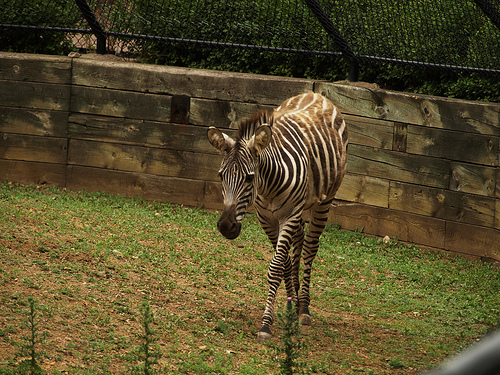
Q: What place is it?
A: It is a field.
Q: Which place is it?
A: It is a field.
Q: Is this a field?
A: Yes, it is a field.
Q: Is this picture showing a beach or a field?
A: It is showing a field.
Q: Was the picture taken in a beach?
A: No, the picture was taken in a field.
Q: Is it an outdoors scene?
A: Yes, it is outdoors.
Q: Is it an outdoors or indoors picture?
A: It is outdoors.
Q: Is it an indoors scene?
A: No, it is outdoors.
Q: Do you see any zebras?
A: Yes, there is a zebra.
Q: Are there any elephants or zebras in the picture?
A: Yes, there is a zebra.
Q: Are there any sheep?
A: No, there are no sheep.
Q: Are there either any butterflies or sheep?
A: No, there are no sheep or butterflies.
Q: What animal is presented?
A: The animal is a zebra.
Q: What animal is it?
A: The animal is a zebra.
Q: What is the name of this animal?
A: This is a zebra.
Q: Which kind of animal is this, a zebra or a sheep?
A: This is a zebra.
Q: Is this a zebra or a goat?
A: This is a zebra.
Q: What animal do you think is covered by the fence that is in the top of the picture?
A: The zebra is covered by the fence.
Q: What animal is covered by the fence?
A: The zebra is covered by the fence.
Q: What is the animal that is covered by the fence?
A: The animal is a zebra.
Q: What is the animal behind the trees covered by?
A: The zebra is covered by the fence.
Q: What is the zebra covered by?
A: The zebra is covered by the fence.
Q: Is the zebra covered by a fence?
A: Yes, the zebra is covered by a fence.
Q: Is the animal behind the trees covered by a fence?
A: Yes, the zebra is covered by a fence.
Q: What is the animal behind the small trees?
A: The animal is a zebra.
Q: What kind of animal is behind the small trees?
A: The animal is a zebra.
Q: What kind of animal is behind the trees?
A: The animal is a zebra.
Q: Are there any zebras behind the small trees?
A: Yes, there is a zebra behind the trees.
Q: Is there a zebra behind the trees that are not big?
A: Yes, there is a zebra behind the trees.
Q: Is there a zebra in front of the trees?
A: No, the zebra is behind the trees.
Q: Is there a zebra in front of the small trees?
A: No, the zebra is behind the trees.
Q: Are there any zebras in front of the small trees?
A: No, the zebra is behind the trees.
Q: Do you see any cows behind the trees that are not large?
A: No, there is a zebra behind the trees.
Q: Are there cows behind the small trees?
A: No, there is a zebra behind the trees.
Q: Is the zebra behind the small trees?
A: Yes, the zebra is behind the trees.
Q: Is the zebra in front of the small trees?
A: No, the zebra is behind the trees.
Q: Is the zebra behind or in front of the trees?
A: The zebra is behind the trees.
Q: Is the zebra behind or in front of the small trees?
A: The zebra is behind the trees.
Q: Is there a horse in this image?
A: No, there are no horses.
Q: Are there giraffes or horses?
A: No, there are no horses or giraffes.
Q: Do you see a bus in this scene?
A: No, there are no buses.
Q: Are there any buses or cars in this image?
A: No, there are no buses or cars.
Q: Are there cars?
A: No, there are no cars.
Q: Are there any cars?
A: No, there are no cars.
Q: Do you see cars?
A: No, there are no cars.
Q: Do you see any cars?
A: No, there are no cars.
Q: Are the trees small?
A: Yes, the trees are small.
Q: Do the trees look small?
A: Yes, the trees are small.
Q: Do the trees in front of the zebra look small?
A: Yes, the trees are small.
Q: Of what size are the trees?
A: The trees are small.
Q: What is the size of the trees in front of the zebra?
A: The trees are small.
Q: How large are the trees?
A: The trees are small.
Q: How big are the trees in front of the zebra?
A: The trees are small.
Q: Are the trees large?
A: No, the trees are small.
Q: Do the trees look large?
A: No, the trees are small.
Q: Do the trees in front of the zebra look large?
A: No, the trees are small.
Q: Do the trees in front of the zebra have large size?
A: No, the trees are small.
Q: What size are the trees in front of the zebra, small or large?
A: The trees are small.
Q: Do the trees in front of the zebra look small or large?
A: The trees are small.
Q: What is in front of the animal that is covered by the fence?
A: The trees are in front of the zebra.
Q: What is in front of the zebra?
A: The trees are in front of the zebra.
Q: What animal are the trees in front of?
A: The trees are in front of the zebra.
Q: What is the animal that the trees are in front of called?
A: The animal is a zebra.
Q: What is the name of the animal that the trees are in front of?
A: The animal is a zebra.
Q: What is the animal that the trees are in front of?
A: The animal is a zebra.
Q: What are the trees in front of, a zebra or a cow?
A: The trees are in front of a zebra.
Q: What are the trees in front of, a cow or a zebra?
A: The trees are in front of a zebra.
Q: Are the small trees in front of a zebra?
A: Yes, the trees are in front of a zebra.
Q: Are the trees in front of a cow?
A: No, the trees are in front of a zebra.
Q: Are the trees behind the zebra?
A: No, the trees are in front of the zebra.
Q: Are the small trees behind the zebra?
A: No, the trees are in front of the zebra.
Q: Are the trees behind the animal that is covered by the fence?
A: No, the trees are in front of the zebra.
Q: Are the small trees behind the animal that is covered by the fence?
A: No, the trees are in front of the zebra.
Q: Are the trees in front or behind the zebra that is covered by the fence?
A: The trees are in front of the zebra.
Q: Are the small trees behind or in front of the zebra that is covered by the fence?
A: The trees are in front of the zebra.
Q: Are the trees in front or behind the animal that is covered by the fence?
A: The trees are in front of the zebra.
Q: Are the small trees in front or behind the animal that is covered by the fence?
A: The trees are in front of the zebra.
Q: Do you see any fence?
A: Yes, there is a fence.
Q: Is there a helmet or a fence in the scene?
A: Yes, there is a fence.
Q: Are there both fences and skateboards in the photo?
A: No, there is a fence but no skateboards.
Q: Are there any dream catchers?
A: No, there are no dream catchers.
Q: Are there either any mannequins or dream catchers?
A: No, there are no dream catchers or mannequins.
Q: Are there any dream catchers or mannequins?
A: No, there are no dream catchers or mannequins.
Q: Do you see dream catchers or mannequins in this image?
A: No, there are no dream catchers or mannequins.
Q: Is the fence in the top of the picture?
A: Yes, the fence is in the top of the image.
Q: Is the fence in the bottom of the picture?
A: No, the fence is in the top of the image.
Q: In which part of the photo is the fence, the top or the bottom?
A: The fence is in the top of the image.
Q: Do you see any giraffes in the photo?
A: No, there are no giraffes.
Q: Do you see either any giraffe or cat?
A: No, there are no giraffes or cats.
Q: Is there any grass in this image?
A: Yes, there is grass.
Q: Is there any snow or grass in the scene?
A: Yes, there is grass.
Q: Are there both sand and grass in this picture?
A: No, there is grass but no sand.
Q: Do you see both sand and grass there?
A: No, there is grass but no sand.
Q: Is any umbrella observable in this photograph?
A: No, there are no umbrellas.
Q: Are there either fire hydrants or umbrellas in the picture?
A: No, there are no umbrellas or fire hydrants.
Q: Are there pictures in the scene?
A: No, there are no pictures.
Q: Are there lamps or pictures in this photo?
A: No, there are no pictures or lamps.